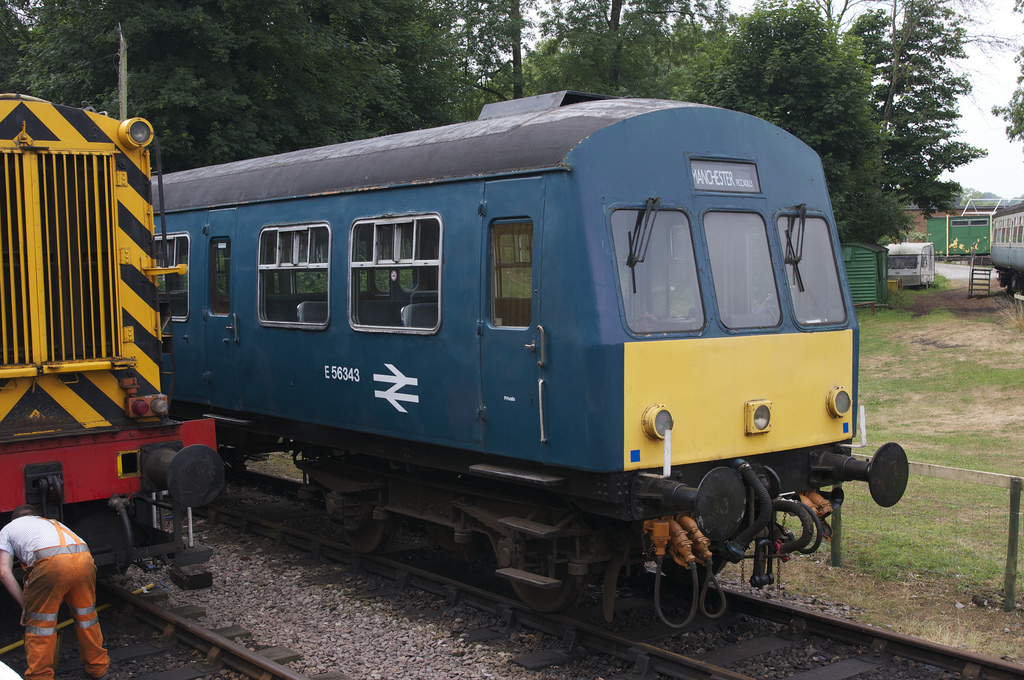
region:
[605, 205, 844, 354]
front windows on the blue train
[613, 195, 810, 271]
wipers on the blue train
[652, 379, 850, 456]
lights on the front of the blue train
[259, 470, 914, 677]
tracks under the blue train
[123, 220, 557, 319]
windows on the side of the blue train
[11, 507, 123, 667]
man bending down in front of a train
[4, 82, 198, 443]
yellow and black stripes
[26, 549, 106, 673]
orange and silver safety pants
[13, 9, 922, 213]
trees behind the train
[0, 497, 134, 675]
man bent over on the tracks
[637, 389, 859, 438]
headlights on the front of the train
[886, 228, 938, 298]
van beside the green shed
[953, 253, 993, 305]
ladder near the caboose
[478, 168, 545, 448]
door on the train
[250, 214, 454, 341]
two windows on the side of the train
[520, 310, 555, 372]
handle of the door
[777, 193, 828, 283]
right black wideshield on train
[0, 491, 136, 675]
man bending over in front of train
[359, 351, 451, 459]
white arrow like design on side of blue train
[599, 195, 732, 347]
left wind shield on front of train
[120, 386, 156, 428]
red tail light on yellow and black train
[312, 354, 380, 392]
white numbers on the side of a blue train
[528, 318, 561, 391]
silver door handle on side door of train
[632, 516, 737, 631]
black hoses with orange connector nozzels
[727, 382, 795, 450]
white center light on yellow portion of train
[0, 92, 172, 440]
black and yellow stripes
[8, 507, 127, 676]
man is bending over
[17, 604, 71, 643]
two silver stripes on the pants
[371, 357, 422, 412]
white design on the side of the train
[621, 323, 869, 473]
yellow paint on the front of the train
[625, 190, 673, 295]
windshield wiper on the front of the train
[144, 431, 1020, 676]
train tracks are on the ground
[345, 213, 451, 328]
window on the side of the train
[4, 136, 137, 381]
vent on the front of the train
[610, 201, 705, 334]
wiper on window surface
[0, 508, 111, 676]
back of bent over man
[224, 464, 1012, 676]
metla rails of train track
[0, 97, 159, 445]
black and yellow train surface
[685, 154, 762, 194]
sign with white words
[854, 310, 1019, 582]
dirt patches in grass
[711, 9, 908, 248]
green leaves on tree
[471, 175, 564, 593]
three steps under door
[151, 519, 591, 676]
gravel between train tracks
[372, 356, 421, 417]
white emblem on blue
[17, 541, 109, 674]
Orange pants with reflective safety tape on them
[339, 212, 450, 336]
white trimmed window on the side of a train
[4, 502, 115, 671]
person bent over in front of a train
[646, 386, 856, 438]
headlights on the front of a train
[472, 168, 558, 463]
door with a window in it on a train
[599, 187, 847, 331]
three panel windshield on a train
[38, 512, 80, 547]
orange suspenders used for holding up pants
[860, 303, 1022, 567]
patchy and unhealthy grass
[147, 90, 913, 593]
The blue train on the track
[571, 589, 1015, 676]
The track under the blue train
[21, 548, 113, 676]
The orange pants on the man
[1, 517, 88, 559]
The white shirt of the man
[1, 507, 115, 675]
The man is bent over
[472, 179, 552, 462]
The door of the train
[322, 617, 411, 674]
rocks on the ground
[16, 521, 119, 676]
a person